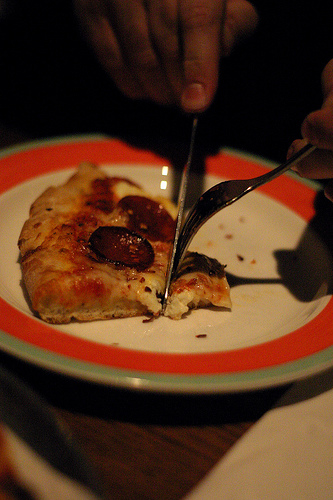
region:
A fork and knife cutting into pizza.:
[161, 105, 314, 307]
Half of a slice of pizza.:
[17, 158, 241, 325]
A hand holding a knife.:
[74, 2, 259, 113]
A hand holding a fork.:
[286, 60, 332, 201]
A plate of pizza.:
[1, 131, 331, 394]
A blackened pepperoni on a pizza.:
[87, 225, 154, 268]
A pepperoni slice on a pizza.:
[119, 194, 174, 240]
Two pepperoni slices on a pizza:
[87, 195, 175, 268]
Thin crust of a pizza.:
[15, 152, 94, 325]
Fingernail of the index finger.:
[181, 79, 206, 110]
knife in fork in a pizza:
[150, 226, 218, 301]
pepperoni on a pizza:
[92, 176, 171, 281]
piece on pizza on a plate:
[21, 157, 232, 332]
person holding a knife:
[119, 18, 226, 117]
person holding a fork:
[270, 101, 332, 186]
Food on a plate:
[28, 147, 281, 362]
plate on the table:
[19, 302, 289, 443]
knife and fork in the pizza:
[146, 59, 277, 300]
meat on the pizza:
[81, 189, 170, 275]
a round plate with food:
[4, 117, 329, 414]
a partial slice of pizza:
[24, 164, 235, 332]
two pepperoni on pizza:
[82, 177, 181, 276]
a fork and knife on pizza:
[125, 119, 292, 343]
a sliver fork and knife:
[142, 119, 317, 357]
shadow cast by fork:
[196, 233, 331, 320]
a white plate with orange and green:
[14, 123, 330, 415]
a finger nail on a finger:
[180, 72, 218, 106]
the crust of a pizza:
[6, 157, 103, 329]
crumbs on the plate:
[195, 203, 266, 346]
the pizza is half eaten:
[20, 162, 230, 319]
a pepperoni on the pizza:
[89, 223, 156, 268]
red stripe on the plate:
[0, 304, 331, 373]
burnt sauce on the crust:
[20, 245, 42, 262]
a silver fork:
[175, 144, 317, 272]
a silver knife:
[164, 113, 196, 305]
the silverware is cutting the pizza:
[162, 111, 314, 308]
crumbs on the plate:
[202, 214, 255, 263]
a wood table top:
[38, 396, 250, 498]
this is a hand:
[58, 9, 284, 125]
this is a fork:
[155, 100, 321, 308]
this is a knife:
[150, 96, 217, 339]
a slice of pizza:
[10, 125, 254, 370]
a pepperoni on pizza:
[81, 203, 161, 288]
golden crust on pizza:
[19, 149, 87, 327]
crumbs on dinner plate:
[179, 195, 273, 368]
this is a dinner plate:
[0, 118, 332, 397]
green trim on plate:
[5, 109, 330, 435]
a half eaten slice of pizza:
[12, 158, 233, 319]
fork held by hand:
[175, 137, 318, 277]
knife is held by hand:
[161, 114, 200, 313]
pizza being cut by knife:
[15, 159, 233, 327]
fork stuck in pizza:
[175, 140, 317, 273]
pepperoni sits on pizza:
[87, 224, 155, 274]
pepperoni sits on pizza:
[116, 192, 176, 242]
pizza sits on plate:
[16, 160, 234, 323]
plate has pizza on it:
[1, 131, 332, 396]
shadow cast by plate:
[0, 349, 332, 424]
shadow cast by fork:
[173, 252, 280, 291]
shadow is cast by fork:
[174, 252, 282, 291]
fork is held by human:
[174, 139, 315, 275]